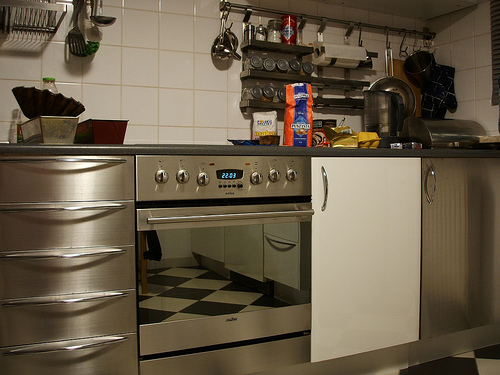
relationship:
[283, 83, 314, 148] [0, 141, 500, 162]
bag on counter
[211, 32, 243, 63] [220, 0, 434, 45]
silver funnel hanging on rack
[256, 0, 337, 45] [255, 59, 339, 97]
canister on a shelf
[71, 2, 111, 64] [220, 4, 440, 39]
utensils hanging on a rack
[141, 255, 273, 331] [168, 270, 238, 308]
reflection on oven door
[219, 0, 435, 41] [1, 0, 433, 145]
rail on wall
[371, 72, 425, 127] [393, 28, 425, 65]
pan on hook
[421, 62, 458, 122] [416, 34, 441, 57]
mitt on hook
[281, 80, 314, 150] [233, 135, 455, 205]
bag on counter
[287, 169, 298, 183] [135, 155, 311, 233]
knob on oven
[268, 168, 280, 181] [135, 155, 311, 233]
knob on oven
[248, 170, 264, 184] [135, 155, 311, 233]
knob on oven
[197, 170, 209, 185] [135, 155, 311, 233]
knob on oven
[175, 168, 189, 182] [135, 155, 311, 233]
knob on oven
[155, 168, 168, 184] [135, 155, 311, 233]
knob on oven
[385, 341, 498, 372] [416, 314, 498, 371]
tiles on floor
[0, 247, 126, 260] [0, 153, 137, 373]
handles on drawers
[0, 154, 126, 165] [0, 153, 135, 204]
handles on drawer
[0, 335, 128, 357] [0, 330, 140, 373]
handles on drawer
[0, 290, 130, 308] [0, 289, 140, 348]
handles on drawer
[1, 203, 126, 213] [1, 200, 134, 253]
handles on drawer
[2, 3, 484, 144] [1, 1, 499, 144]
tiles on walls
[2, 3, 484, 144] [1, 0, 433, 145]
tiles on wall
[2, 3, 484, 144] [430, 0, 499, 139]
tiles on wall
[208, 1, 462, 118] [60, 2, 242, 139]
kitchen appliances hanging on wall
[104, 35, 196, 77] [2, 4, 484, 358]
wall in kitchen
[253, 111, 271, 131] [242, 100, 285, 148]
flour in packet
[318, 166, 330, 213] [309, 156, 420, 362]
handle on cabinet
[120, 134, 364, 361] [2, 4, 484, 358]
oven in kitchen